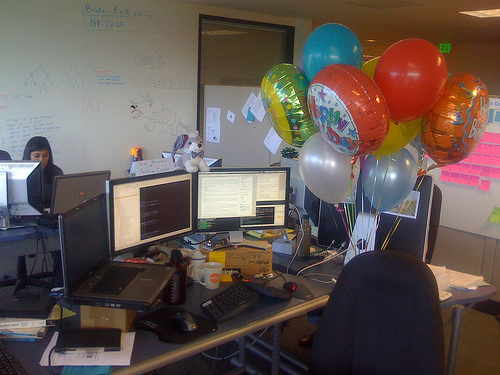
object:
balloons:
[302, 22, 364, 83]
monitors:
[106, 167, 291, 257]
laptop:
[57, 192, 179, 311]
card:
[127, 156, 177, 179]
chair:
[309, 249, 445, 373]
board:
[0, 0, 200, 179]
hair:
[32, 141, 47, 151]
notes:
[439, 169, 452, 181]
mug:
[194, 261, 222, 290]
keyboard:
[199, 279, 261, 324]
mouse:
[172, 310, 199, 331]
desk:
[0, 234, 351, 375]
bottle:
[167, 249, 188, 304]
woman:
[23, 136, 65, 209]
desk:
[0, 203, 62, 260]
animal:
[170, 132, 211, 173]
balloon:
[373, 38, 448, 124]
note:
[477, 178, 493, 192]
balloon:
[297, 131, 361, 203]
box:
[208, 239, 274, 281]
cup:
[186, 250, 206, 282]